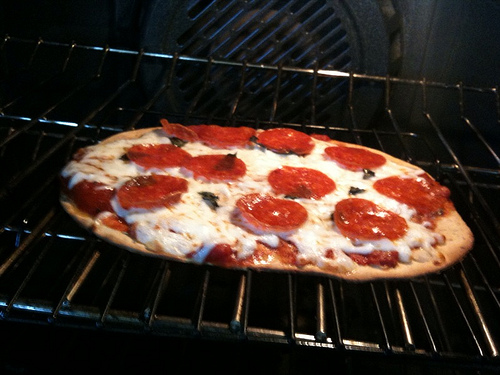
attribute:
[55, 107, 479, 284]
pizza — small, pepperoni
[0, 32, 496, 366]
rack — black, metal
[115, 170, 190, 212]
pepperoni — sliced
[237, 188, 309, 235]
pepperoni — round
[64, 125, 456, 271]
cheese — melted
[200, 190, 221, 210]
leaf — small, basil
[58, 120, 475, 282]
crust — toasted, thin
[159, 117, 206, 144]
pepperoni — sticking up, sliced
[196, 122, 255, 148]
pepperoni — sliced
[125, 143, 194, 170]
pepperoni — round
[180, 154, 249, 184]
pepperoni — round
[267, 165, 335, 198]
pepperoni — round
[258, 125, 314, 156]
pepperoni — round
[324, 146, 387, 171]
pepperoni — round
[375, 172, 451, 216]
pepperoni — round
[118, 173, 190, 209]
pepperoni — round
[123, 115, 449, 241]
pepperoni — red